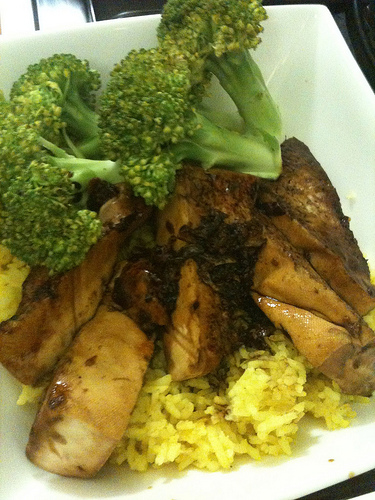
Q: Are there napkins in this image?
A: No, there are no napkins.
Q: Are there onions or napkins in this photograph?
A: No, there are no napkins or onions.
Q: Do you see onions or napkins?
A: No, there are no napkins or onions.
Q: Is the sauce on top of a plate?
A: Yes, the sauce is on top of a plate.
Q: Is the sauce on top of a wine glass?
A: No, the sauce is on top of a plate.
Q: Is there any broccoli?
A: Yes, there is broccoli.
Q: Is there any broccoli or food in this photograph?
A: Yes, there is broccoli.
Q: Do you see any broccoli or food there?
A: Yes, there is broccoli.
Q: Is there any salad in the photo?
A: No, there is no salad.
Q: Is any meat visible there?
A: Yes, there is meat.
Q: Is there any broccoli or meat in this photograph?
A: Yes, there is meat.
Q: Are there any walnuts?
A: No, there are no walnuts.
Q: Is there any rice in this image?
A: Yes, there is rice.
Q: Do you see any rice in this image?
A: Yes, there is rice.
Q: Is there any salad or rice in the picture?
A: Yes, there is rice.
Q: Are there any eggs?
A: No, there are no eggs.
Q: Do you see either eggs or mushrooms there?
A: No, there are no eggs or mushrooms.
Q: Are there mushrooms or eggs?
A: No, there are no eggs or mushrooms.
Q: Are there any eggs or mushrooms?
A: No, there are no eggs or mushrooms.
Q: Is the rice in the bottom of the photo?
A: Yes, the rice is in the bottom of the image.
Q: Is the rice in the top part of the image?
A: No, the rice is in the bottom of the image.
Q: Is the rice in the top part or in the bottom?
A: The rice is in the bottom of the image.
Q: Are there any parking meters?
A: No, there are no parking meters.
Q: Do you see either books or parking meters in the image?
A: No, there are no parking meters or books.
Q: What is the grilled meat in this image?
A: The meat is chicken.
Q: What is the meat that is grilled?
A: The meat is chicken.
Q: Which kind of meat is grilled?
A: The meat is chicken.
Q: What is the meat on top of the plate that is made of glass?
A: The meat is chicken.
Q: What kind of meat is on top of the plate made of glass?
A: The meat is chicken.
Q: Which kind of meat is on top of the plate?
A: The meat is chicken.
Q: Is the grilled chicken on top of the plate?
A: Yes, the chicken is on top of the plate.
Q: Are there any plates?
A: Yes, there is a plate.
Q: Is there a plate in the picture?
A: Yes, there is a plate.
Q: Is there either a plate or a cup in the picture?
A: Yes, there is a plate.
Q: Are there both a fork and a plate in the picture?
A: No, there is a plate but no forks.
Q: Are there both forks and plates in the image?
A: No, there is a plate but no forks.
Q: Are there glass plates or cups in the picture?
A: Yes, there is a glass plate.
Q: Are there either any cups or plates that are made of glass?
A: Yes, the plate is made of glass.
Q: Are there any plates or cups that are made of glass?
A: Yes, the plate is made of glass.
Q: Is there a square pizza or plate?
A: Yes, there is a square plate.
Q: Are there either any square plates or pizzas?
A: Yes, there is a square plate.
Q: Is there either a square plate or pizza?
A: Yes, there is a square plate.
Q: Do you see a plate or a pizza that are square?
A: Yes, the plate is square.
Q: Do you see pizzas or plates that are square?
A: Yes, the plate is square.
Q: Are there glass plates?
A: Yes, there is a plate that is made of glass.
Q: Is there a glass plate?
A: Yes, there is a plate that is made of glass.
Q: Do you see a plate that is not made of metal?
A: Yes, there is a plate that is made of glass.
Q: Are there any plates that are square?
A: Yes, there is a square plate.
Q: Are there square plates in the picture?
A: Yes, there is a square plate.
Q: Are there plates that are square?
A: Yes, there is a plate that is square.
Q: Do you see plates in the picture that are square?
A: Yes, there is a plate that is square.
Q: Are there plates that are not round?
A: Yes, there is a square plate.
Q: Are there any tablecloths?
A: No, there are no tablecloths.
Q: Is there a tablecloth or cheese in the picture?
A: No, there are no tablecloths or cheese.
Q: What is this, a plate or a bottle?
A: This is a plate.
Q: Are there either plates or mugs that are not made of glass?
A: No, there is a plate but it is made of glass.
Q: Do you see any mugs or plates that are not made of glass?
A: No, there is a plate but it is made of glass.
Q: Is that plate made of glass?
A: Yes, the plate is made of glass.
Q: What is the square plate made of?
A: The plate is made of glass.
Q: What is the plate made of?
A: The plate is made of glass.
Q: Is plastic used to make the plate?
A: No, the plate is made of glass.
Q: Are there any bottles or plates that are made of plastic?
A: No, there is a plate but it is made of glass.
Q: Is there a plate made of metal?
A: No, there is a plate but it is made of glass.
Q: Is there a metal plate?
A: No, there is a plate but it is made of glass.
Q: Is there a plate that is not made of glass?
A: No, there is a plate but it is made of glass.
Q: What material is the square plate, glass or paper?
A: The plate is made of glass.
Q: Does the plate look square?
A: Yes, the plate is square.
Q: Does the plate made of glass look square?
A: Yes, the plate is square.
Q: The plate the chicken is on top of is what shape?
A: The plate is square.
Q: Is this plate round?
A: No, the plate is square.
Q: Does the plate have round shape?
A: No, the plate is square.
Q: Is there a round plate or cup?
A: No, there is a plate but it is square.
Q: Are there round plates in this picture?
A: No, there is a plate but it is square.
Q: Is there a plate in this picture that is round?
A: No, there is a plate but it is square.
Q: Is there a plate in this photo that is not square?
A: No, there is a plate but it is square.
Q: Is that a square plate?
A: Yes, that is a square plate.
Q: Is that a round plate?
A: No, that is a square plate.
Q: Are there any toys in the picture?
A: No, there are no toys.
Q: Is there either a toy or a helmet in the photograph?
A: No, there are no toys or helmets.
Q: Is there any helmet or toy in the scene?
A: No, there are no toys or helmets.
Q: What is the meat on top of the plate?
A: The meat is chicken.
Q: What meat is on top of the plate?
A: The meat is chicken.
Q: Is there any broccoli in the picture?
A: Yes, there is broccoli.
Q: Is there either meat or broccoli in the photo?
A: Yes, there is broccoli.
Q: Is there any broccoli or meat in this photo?
A: Yes, there is broccoli.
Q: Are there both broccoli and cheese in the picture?
A: No, there is broccoli but no cheese.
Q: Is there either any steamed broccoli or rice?
A: Yes, there is steamed broccoli.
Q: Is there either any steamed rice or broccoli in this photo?
A: Yes, there is steamed broccoli.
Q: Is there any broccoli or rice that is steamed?
A: Yes, the broccoli is steamed.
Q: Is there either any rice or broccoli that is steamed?
A: Yes, the broccoli is steamed.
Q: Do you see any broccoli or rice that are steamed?
A: Yes, the broccoli is steamed.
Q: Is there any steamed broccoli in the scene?
A: Yes, there is steamed broccoli.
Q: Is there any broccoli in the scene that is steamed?
A: Yes, there is broccoli that is steamed.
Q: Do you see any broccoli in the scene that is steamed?
A: Yes, there is broccoli that is steamed.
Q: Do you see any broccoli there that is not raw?
A: Yes, there is steamed broccoli.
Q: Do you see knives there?
A: No, there are no knives.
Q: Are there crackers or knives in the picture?
A: No, there are no knives or crackers.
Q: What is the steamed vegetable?
A: The vegetable is broccoli.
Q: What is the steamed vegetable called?
A: The vegetable is broccoli.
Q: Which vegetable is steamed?
A: The vegetable is broccoli.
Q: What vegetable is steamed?
A: The vegetable is broccoli.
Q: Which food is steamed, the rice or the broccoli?
A: The broccoli is steamed.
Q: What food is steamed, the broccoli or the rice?
A: The broccoli is steamed.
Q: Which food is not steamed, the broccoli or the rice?
A: The rice is not steamed.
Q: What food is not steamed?
A: The food is rice.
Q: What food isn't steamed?
A: The food is rice.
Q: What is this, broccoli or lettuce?
A: This is broccoli.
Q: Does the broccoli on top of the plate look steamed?
A: Yes, the broccoli is steamed.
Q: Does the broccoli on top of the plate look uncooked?
A: No, the broccoli is steamed.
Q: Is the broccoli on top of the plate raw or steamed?
A: The broccoli is steamed.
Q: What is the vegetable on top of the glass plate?
A: The vegetable is broccoli.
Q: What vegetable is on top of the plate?
A: The vegetable is broccoli.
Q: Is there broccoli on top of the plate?
A: Yes, there is broccoli on top of the plate.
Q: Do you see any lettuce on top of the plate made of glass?
A: No, there is broccoli on top of the plate.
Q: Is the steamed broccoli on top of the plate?
A: Yes, the broccoli is on top of the plate.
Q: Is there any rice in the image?
A: Yes, there is rice.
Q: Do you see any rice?
A: Yes, there is rice.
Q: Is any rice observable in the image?
A: Yes, there is rice.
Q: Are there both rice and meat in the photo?
A: Yes, there are both rice and meat.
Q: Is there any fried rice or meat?
A: Yes, there is fried rice.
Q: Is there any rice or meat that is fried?
A: Yes, the rice is fried.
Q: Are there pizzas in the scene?
A: No, there are no pizzas.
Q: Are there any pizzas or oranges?
A: No, there are no pizzas or oranges.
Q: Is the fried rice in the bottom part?
A: Yes, the rice is in the bottom of the image.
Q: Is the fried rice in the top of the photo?
A: No, the rice is in the bottom of the image.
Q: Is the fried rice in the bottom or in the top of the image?
A: The rice is in the bottom of the image.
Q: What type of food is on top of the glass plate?
A: The food is rice.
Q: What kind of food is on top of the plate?
A: The food is rice.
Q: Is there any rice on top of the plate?
A: Yes, there is rice on top of the plate.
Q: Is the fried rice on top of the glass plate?
A: Yes, the rice is on top of the plate.